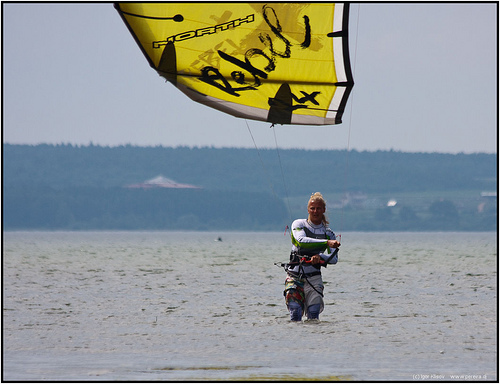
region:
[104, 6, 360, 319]
a woman parasailing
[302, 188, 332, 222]
blonde haired lady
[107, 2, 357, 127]
a yellow black and white sail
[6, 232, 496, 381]
thick mulky water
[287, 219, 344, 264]
blue and green shirt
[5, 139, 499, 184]
trees in the horizon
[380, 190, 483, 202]
a field to right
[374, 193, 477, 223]
bushes on the right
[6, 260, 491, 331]
choppy water in front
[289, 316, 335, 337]
knees down in water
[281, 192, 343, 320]
Happy person flying kite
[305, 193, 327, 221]
Head of kite flier.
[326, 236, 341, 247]
Hand of kite flier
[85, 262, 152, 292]
beige sandy beach area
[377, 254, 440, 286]
Beige sandy beach area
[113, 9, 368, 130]
Part of bright yellow kite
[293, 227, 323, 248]
Arm of kite flier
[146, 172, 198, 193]
White churning beach surf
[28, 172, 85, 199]
Cold blue ocean water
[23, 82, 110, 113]
hazy cold ocean sky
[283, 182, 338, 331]
person flying kite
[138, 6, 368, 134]
yellow and black kite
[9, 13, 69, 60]
white clouds in blue sky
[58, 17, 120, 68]
white clouds in blue sky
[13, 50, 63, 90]
white clouds in blue sky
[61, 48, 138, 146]
white clouds in blue sky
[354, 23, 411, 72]
white clouds in blue sky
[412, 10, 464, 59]
white clouds in blue sky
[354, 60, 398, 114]
white clouds in blue sky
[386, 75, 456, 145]
white clouds in blue sky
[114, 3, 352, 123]
black and yellow parachut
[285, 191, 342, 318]
woman water parachuting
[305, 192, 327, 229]
woman with long blond hair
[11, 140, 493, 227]
tree covered hill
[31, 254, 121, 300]
ripples on grey water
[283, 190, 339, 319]
woman wearing a wet suit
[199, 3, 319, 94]
black letters on the parachut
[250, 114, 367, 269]
lines holding the parachut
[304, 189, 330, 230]
woman's hair is blowing in the wind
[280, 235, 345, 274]
woman holding onto the parachut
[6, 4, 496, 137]
cloud cover in sky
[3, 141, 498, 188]
haze over horizon of trees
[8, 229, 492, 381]
body of choppy water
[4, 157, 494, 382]
hill of land overlooking water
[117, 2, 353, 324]
woman under yellow parasail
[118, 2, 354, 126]
yellow and black parasail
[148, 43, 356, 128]
white edge of parasail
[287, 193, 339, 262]
white and green sleeve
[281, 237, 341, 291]
two hands on poles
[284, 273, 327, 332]
two legs in water